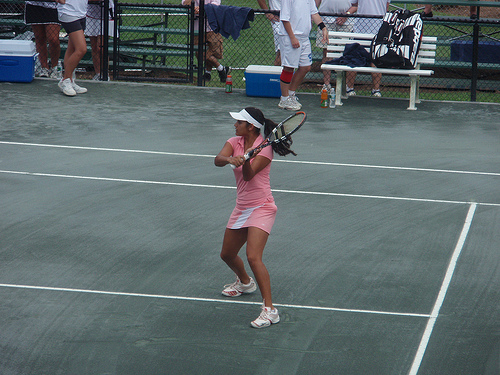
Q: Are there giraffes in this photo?
A: No, there are no giraffes.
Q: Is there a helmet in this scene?
A: No, there are no helmets.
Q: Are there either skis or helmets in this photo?
A: No, there are no helmets or skis.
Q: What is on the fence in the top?
A: The jacket is on the fence.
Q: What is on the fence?
A: The jacket is on the fence.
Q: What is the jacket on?
A: The jacket is on the fence.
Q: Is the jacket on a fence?
A: Yes, the jacket is on a fence.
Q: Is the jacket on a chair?
A: No, the jacket is on a fence.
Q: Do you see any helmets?
A: No, there are no helmets.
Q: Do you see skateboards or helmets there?
A: No, there are no helmets or skateboards.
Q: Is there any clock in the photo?
A: No, there are no clocks.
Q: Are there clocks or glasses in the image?
A: No, there are no clocks or glasses.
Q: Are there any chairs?
A: No, there are no chairs.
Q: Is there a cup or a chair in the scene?
A: No, there are no chairs or cups.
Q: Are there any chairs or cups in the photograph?
A: No, there are no chairs or cups.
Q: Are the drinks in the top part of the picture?
A: Yes, the drinks are in the top of the image.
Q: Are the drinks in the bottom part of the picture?
A: No, the drinks are in the top of the image.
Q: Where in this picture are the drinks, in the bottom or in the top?
A: The drinks are in the top of the image.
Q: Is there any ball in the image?
A: No, there are no balls.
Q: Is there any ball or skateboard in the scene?
A: No, there are no balls or skateboards.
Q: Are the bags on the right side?
A: Yes, the bags are on the right of the image.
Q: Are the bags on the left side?
A: No, the bags are on the right of the image.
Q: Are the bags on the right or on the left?
A: The bags are on the right of the image.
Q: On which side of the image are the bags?
A: The bags are on the right of the image.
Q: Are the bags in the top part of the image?
A: Yes, the bags are in the top of the image.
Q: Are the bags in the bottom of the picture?
A: No, the bags are in the top of the image.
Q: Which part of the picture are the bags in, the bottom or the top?
A: The bags are in the top of the image.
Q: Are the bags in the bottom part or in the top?
A: The bags are in the top of the image.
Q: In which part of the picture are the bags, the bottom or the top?
A: The bags are in the top of the image.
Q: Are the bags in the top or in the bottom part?
A: The bags are in the top of the image.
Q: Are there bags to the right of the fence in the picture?
A: Yes, there are bags to the right of the fence.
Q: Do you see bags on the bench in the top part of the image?
A: Yes, there are bags on the bench.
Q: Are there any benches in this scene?
A: Yes, there is a bench.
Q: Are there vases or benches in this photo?
A: Yes, there is a bench.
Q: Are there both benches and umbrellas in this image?
A: No, there is a bench but no umbrellas.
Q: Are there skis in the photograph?
A: No, there are no skis.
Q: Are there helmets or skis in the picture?
A: No, there are no skis or helmets.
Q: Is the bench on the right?
A: Yes, the bench is on the right of the image.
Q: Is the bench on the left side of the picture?
A: No, the bench is on the right of the image.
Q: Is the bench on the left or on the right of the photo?
A: The bench is on the right of the image.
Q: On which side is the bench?
A: The bench is on the right of the image.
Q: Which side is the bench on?
A: The bench is on the right of the image.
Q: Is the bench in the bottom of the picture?
A: No, the bench is in the top of the image.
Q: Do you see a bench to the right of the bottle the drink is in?
A: Yes, there is a bench to the right of the bottle.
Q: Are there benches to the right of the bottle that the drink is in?
A: Yes, there is a bench to the right of the bottle.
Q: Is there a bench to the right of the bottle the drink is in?
A: Yes, there is a bench to the right of the bottle.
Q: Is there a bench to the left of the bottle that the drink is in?
A: No, the bench is to the right of the bottle.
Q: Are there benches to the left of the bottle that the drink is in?
A: No, the bench is to the right of the bottle.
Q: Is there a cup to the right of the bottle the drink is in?
A: No, there is a bench to the right of the bottle.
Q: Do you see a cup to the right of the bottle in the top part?
A: No, there is a bench to the right of the bottle.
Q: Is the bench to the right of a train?
A: No, the bench is to the right of a bottle.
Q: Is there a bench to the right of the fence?
A: Yes, there is a bench to the right of the fence.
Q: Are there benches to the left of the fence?
A: No, the bench is to the right of the fence.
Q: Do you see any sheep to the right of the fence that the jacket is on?
A: No, there is a bench to the right of the fence.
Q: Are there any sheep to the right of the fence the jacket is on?
A: No, there is a bench to the right of the fence.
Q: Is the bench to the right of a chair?
A: No, the bench is to the right of the fence.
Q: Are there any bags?
A: Yes, there is a bag.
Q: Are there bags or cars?
A: Yes, there is a bag.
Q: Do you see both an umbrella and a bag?
A: No, there is a bag but no umbrellas.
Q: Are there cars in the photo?
A: No, there are no cars.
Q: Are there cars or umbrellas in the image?
A: No, there are no cars or umbrellas.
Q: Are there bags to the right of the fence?
A: Yes, there is a bag to the right of the fence.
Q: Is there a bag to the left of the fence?
A: No, the bag is to the right of the fence.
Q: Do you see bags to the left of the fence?
A: No, the bag is to the right of the fence.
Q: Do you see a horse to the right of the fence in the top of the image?
A: No, there is a bag to the right of the fence.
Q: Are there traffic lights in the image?
A: No, there are no traffic lights.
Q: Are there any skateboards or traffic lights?
A: No, there are no traffic lights or skateboards.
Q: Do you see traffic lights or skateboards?
A: No, there are no traffic lights or skateboards.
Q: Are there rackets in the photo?
A: Yes, there is a racket.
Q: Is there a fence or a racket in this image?
A: Yes, there is a racket.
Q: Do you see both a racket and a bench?
A: Yes, there are both a racket and a bench.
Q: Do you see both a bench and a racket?
A: Yes, there are both a racket and a bench.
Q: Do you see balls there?
A: No, there are no balls.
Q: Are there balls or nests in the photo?
A: No, there are no balls or nests.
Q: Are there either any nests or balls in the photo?
A: No, there are no balls or nests.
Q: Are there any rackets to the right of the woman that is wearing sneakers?
A: Yes, there is a racket to the right of the woman.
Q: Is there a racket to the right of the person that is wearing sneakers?
A: Yes, there is a racket to the right of the woman.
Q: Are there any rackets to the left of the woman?
A: No, the racket is to the right of the woman.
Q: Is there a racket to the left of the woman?
A: No, the racket is to the right of the woman.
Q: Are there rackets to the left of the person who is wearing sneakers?
A: No, the racket is to the right of the woman.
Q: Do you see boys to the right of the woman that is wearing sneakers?
A: No, there is a racket to the right of the woman.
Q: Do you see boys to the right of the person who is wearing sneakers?
A: No, there is a racket to the right of the woman.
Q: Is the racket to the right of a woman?
A: Yes, the racket is to the right of a woman.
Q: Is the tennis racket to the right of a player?
A: No, the tennis racket is to the right of a woman.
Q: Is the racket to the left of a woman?
A: No, the racket is to the right of a woman.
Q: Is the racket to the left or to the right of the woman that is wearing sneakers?
A: The racket is to the right of the woman.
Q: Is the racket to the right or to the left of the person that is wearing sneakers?
A: The racket is to the right of the woman.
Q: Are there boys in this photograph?
A: No, there are no boys.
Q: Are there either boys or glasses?
A: No, there are no boys or glasses.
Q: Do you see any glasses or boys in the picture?
A: No, there are no boys or glasses.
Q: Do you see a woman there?
A: Yes, there is a woman.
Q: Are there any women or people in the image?
A: Yes, there is a woman.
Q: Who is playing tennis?
A: The woman is playing tennis.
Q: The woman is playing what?
A: The woman is playing tennis.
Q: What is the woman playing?
A: The woman is playing tennis.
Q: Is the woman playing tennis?
A: Yes, the woman is playing tennis.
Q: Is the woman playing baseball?
A: No, the woman is playing tennis.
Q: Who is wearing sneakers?
A: The woman is wearing sneakers.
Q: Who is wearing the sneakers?
A: The woman is wearing sneakers.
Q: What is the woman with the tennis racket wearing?
A: The woman is wearing sneakers.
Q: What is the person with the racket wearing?
A: The woman is wearing sneakers.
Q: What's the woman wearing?
A: The woman is wearing sneakers.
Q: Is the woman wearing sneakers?
A: Yes, the woman is wearing sneakers.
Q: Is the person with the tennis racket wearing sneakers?
A: Yes, the woman is wearing sneakers.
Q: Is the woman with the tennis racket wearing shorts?
A: No, the woman is wearing sneakers.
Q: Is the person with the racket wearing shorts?
A: No, the woman is wearing sneakers.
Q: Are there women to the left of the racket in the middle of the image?
A: Yes, there is a woman to the left of the tennis racket.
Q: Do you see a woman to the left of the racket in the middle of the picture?
A: Yes, there is a woman to the left of the tennis racket.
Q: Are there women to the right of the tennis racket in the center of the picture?
A: No, the woman is to the left of the racket.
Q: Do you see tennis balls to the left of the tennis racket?
A: No, there is a woman to the left of the tennis racket.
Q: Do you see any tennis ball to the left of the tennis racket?
A: No, there is a woman to the left of the tennis racket.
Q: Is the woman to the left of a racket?
A: Yes, the woman is to the left of a racket.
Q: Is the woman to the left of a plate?
A: No, the woman is to the left of a racket.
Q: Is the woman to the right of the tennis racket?
A: No, the woman is to the left of the tennis racket.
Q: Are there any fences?
A: Yes, there is a fence.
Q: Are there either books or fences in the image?
A: Yes, there is a fence.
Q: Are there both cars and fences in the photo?
A: No, there is a fence but no cars.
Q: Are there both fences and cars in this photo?
A: No, there is a fence but no cars.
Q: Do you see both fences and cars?
A: No, there is a fence but no cars.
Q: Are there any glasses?
A: No, there are no glasses.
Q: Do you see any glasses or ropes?
A: No, there are no glasses or ropes.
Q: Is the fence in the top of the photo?
A: Yes, the fence is in the top of the image.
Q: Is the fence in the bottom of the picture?
A: No, the fence is in the top of the image.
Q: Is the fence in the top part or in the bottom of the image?
A: The fence is in the top of the image.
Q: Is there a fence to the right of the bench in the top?
A: No, the fence is to the left of the bench.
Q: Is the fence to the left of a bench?
A: Yes, the fence is to the left of a bench.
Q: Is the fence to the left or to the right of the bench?
A: The fence is to the left of the bench.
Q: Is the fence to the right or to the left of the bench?
A: The fence is to the left of the bench.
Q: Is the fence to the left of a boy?
A: No, the fence is to the left of the bag.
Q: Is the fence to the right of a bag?
A: No, the fence is to the left of a bag.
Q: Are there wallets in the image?
A: No, there are no wallets.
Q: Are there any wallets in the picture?
A: No, there are no wallets.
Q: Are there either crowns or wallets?
A: No, there are no wallets or crowns.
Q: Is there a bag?
A: Yes, there is a bag.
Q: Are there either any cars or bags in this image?
A: Yes, there is a bag.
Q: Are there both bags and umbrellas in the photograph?
A: No, there is a bag but no umbrellas.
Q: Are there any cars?
A: No, there are no cars.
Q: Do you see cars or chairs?
A: No, there are no cars or chairs.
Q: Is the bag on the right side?
A: Yes, the bag is on the right of the image.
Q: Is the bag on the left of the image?
A: No, the bag is on the right of the image.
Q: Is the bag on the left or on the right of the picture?
A: The bag is on the right of the image.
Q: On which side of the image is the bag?
A: The bag is on the right of the image.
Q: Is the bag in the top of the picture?
A: Yes, the bag is in the top of the image.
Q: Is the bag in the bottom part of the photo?
A: No, the bag is in the top of the image.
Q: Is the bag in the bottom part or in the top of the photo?
A: The bag is in the top of the image.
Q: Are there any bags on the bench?
A: Yes, there is a bag on the bench.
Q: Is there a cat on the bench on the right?
A: No, there is a bag on the bench.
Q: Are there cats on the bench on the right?
A: No, there is a bag on the bench.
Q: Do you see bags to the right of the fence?
A: Yes, there is a bag to the right of the fence.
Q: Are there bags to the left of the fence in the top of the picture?
A: No, the bag is to the right of the fence.